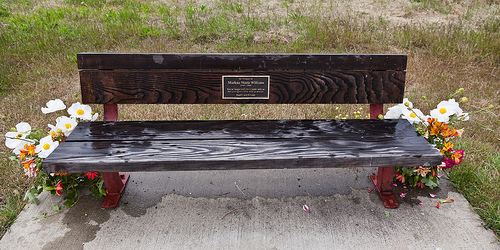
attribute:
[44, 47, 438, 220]
bench — outdoors, soaked, vacant, wet, wooden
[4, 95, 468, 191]
flowers — white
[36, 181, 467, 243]
concrete — wet